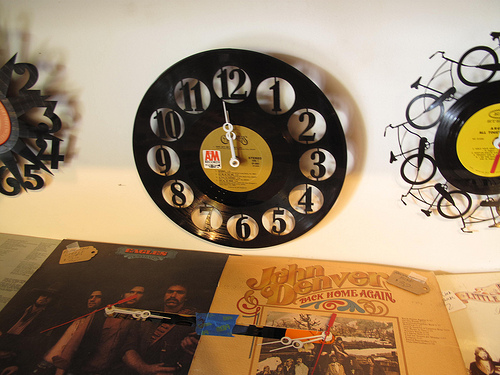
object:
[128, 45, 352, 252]
clock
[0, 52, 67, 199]
deco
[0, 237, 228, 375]
album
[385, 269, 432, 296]
tag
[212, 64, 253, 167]
hour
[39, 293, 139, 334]
eagle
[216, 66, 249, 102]
number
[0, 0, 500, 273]
wall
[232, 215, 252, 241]
numbers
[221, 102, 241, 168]
arms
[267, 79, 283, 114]
number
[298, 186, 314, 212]
number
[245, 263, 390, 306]
name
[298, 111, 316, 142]
number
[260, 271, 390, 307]
word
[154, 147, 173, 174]
number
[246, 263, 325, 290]
john